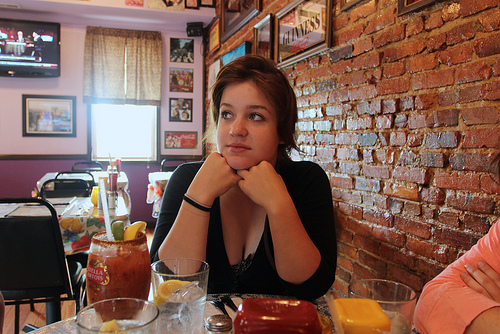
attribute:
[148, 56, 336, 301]
woman — sitting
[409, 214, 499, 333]
shirt — peach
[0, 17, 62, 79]
television — on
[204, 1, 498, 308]
wall — brick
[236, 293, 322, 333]
bottle — upside down, red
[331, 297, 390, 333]
mustard — upside down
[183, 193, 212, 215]
wristband — black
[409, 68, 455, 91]
brick — brown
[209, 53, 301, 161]
hair — brown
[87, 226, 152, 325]
glass — big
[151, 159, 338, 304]
blouse — black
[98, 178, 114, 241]
straw — white